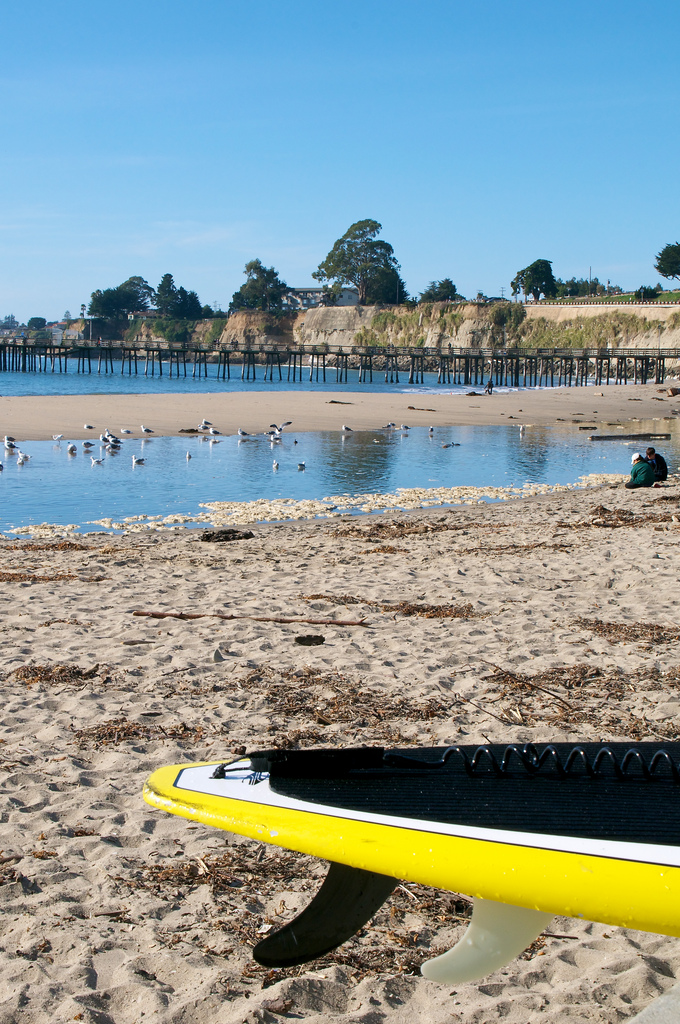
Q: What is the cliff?
A: Very tall.